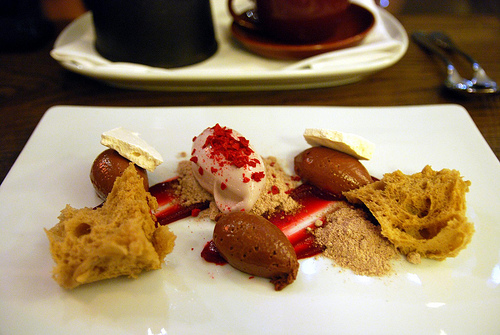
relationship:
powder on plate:
[309, 203, 399, 276] [1, 100, 470, 331]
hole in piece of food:
[73, 220, 91, 236] [42, 160, 178, 290]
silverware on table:
[407, 23, 483, 100] [0, 17, 483, 203]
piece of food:
[361, 183, 468, 249] [337, 165, 472, 263]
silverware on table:
[415, 24, 498, 104] [11, 9, 494, 149]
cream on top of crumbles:
[187, 122, 266, 211] [264, 159, 290, 206]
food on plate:
[289, 125, 372, 190] [1, 100, 470, 331]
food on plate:
[42, 168, 175, 289] [1, 100, 470, 331]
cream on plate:
[187, 122, 266, 215] [1, 100, 470, 331]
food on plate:
[210, 210, 297, 279] [1, 100, 470, 331]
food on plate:
[350, 160, 477, 265] [1, 100, 470, 331]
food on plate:
[42, 160, 178, 290] [1, 100, 470, 331]